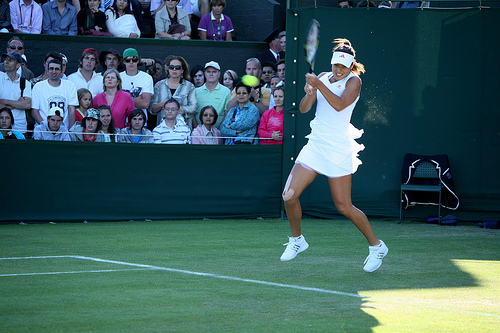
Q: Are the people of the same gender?
A: No, they are both male and female.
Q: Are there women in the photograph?
A: Yes, there is a woman.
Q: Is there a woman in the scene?
A: Yes, there is a woman.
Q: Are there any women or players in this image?
A: Yes, there is a woman.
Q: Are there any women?
A: Yes, there is a woman.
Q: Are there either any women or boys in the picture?
A: Yes, there is a woman.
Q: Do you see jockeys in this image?
A: No, there are no jockeys.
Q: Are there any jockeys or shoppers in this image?
A: No, there are no jockeys or shoppers.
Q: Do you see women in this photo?
A: Yes, there is a woman.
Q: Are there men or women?
A: Yes, there is a woman.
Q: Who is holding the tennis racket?
A: The woman is holding the tennis racket.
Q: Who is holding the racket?
A: The woman is holding the tennis racket.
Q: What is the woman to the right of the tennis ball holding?
A: The woman is holding the tennis racket.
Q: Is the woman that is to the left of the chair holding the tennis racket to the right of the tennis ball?
A: Yes, the woman is holding the racket.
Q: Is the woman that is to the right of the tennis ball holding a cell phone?
A: No, the woman is holding the racket.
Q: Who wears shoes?
A: The woman wears shoes.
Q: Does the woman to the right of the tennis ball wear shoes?
A: Yes, the woman wears shoes.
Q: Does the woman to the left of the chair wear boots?
A: No, the woman wears shoes.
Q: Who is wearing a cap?
A: The woman is wearing a cap.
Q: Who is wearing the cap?
A: The woman is wearing a cap.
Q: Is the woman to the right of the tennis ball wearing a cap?
A: Yes, the woman is wearing a cap.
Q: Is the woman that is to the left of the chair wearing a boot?
A: No, the woman is wearing a cap.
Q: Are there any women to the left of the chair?
A: Yes, there is a woman to the left of the chair.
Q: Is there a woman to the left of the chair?
A: Yes, there is a woman to the left of the chair.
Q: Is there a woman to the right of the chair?
A: No, the woman is to the left of the chair.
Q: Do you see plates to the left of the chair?
A: No, there is a woman to the left of the chair.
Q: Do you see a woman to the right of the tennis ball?
A: Yes, there is a woman to the right of the tennis ball.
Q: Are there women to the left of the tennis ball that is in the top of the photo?
A: No, the woman is to the right of the tennis ball.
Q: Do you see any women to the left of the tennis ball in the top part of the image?
A: No, the woman is to the right of the tennis ball.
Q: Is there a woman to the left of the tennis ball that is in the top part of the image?
A: No, the woman is to the right of the tennis ball.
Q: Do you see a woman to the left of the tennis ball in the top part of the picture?
A: No, the woman is to the right of the tennis ball.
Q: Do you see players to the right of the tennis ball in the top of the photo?
A: No, there is a woman to the right of the tennis ball.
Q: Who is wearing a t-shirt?
A: The woman is wearing a t-shirt.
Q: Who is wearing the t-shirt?
A: The woman is wearing a t-shirt.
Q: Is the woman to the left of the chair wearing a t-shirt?
A: Yes, the woman is wearing a t-shirt.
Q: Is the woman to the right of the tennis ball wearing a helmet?
A: No, the woman is wearing a t-shirt.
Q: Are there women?
A: Yes, there is a woman.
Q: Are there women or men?
A: Yes, there is a woman.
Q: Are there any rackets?
A: Yes, there is a racket.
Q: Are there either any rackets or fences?
A: Yes, there is a racket.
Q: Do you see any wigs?
A: No, there are no wigs.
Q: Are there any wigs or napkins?
A: No, there are no wigs or napkins.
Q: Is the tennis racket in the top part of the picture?
A: Yes, the tennis racket is in the top of the image.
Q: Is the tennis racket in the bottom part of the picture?
A: No, the tennis racket is in the top of the image.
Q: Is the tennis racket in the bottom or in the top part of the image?
A: The tennis racket is in the top of the image.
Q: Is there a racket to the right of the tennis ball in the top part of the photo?
A: Yes, there is a racket to the right of the tennis ball.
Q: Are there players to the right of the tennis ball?
A: No, there is a racket to the right of the tennis ball.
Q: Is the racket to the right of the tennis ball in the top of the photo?
A: Yes, the racket is to the right of the tennis ball.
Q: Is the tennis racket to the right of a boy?
A: No, the tennis racket is to the right of the tennis ball.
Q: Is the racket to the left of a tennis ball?
A: No, the racket is to the right of a tennis ball.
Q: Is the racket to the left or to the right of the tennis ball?
A: The racket is to the right of the tennis ball.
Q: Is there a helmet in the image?
A: No, there are no helmets.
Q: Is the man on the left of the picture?
A: Yes, the man is on the left of the image.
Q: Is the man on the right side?
A: No, the man is on the left of the image.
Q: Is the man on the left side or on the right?
A: The man is on the left of the image.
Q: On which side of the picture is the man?
A: The man is on the left of the image.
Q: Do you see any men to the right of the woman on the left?
A: Yes, there is a man to the right of the woman.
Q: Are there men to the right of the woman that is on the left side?
A: Yes, there is a man to the right of the woman.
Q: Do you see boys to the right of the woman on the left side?
A: No, there is a man to the right of the woman.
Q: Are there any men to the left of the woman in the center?
A: Yes, there is a man to the left of the woman.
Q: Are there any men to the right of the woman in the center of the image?
A: No, the man is to the left of the woman.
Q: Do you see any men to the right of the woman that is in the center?
A: No, the man is to the left of the woman.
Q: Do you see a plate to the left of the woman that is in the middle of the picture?
A: No, there is a man to the left of the woman.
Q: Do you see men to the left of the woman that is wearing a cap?
A: Yes, there is a man to the left of the woman.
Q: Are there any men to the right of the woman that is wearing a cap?
A: No, the man is to the left of the woman.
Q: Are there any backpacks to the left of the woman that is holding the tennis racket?
A: No, there is a man to the left of the woman.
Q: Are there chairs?
A: Yes, there is a chair.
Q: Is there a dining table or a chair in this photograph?
A: Yes, there is a chair.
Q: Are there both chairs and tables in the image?
A: No, there is a chair but no tables.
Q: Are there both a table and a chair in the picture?
A: No, there is a chair but no tables.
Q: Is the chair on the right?
A: Yes, the chair is on the right of the image.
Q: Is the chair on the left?
A: No, the chair is on the right of the image.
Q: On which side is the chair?
A: The chair is on the right of the image.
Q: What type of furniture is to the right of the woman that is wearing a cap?
A: The piece of furniture is a chair.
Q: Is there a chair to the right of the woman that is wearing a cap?
A: Yes, there is a chair to the right of the woman.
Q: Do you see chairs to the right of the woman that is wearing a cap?
A: Yes, there is a chair to the right of the woman.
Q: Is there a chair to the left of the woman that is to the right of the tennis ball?
A: No, the chair is to the right of the woman.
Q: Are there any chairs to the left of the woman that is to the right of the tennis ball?
A: No, the chair is to the right of the woman.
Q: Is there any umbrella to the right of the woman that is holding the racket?
A: No, there is a chair to the right of the woman.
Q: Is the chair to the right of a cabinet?
A: No, the chair is to the right of the woman.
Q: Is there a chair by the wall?
A: Yes, there is a chair by the wall.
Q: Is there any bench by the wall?
A: No, there is a chair by the wall.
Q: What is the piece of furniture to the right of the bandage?
A: The piece of furniture is a chair.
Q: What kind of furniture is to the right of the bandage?
A: The piece of furniture is a chair.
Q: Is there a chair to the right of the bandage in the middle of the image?
A: Yes, there is a chair to the right of the bandage.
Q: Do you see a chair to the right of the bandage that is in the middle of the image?
A: Yes, there is a chair to the right of the bandage.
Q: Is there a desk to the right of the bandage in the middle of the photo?
A: No, there is a chair to the right of the bandage.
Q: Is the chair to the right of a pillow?
A: No, the chair is to the right of the bandage.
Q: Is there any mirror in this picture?
A: No, there are no mirrors.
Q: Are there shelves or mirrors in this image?
A: No, there are no mirrors or shelves.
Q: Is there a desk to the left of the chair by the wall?
A: No, there is a bandage to the left of the chair.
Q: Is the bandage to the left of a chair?
A: Yes, the bandage is to the left of a chair.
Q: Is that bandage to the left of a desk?
A: No, the bandage is to the left of a chair.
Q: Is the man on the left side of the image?
A: Yes, the man is on the left of the image.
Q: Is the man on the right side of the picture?
A: No, the man is on the left of the image.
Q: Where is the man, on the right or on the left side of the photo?
A: The man is on the left of the image.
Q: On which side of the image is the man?
A: The man is on the left of the image.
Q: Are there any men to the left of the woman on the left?
A: Yes, there is a man to the left of the woman.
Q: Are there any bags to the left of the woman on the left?
A: No, there is a man to the left of the woman.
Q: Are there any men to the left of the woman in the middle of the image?
A: Yes, there is a man to the left of the woman.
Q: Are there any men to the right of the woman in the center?
A: No, the man is to the left of the woman.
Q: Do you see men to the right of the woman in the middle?
A: No, the man is to the left of the woman.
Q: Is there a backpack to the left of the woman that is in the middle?
A: No, there is a man to the left of the woman.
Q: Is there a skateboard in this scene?
A: No, there are no skateboards.